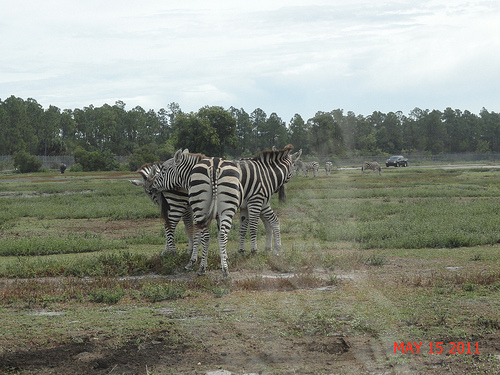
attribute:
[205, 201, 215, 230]
hair — white